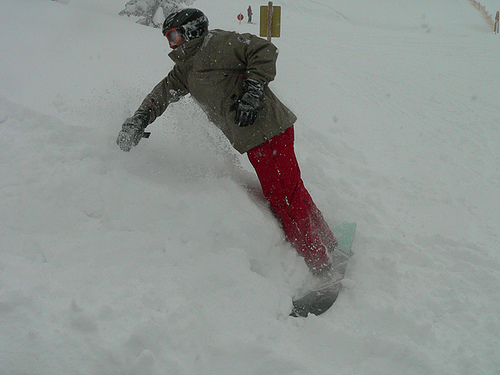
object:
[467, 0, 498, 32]
fence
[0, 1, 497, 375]
trail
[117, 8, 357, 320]
person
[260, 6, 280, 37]
sign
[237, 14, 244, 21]
sign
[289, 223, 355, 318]
snowboard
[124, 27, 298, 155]
jacket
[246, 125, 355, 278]
pants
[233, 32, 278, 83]
sleeve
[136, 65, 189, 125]
sleeve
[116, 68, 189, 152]
arm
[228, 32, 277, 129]
arm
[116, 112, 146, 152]
glove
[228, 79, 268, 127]
glove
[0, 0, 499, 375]
hill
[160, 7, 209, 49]
head